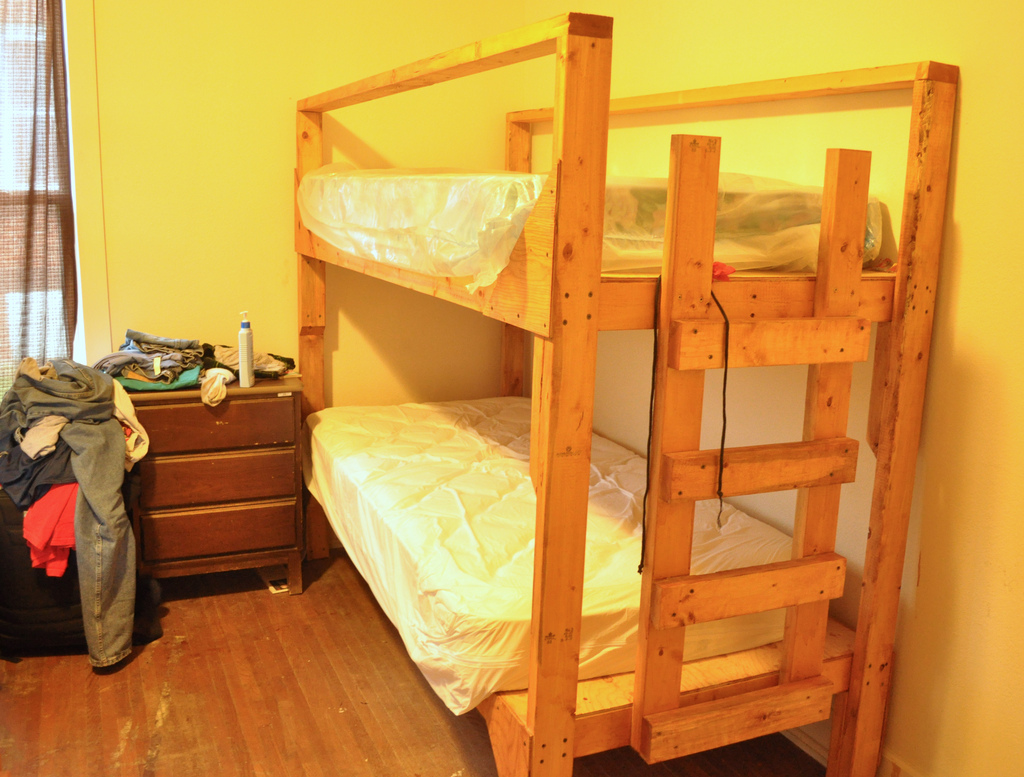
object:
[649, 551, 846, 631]
slat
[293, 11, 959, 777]
bed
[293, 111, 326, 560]
slat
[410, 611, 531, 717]
mattress protector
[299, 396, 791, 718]
mattress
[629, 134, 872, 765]
ladder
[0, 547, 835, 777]
floor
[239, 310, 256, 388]
bottle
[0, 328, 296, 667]
clothing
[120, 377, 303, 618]
dresser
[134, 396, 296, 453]
drawer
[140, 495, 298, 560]
drawer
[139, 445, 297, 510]
drawer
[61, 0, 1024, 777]
wall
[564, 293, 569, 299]
screw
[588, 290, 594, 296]
screw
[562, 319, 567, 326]
screw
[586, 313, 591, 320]
screw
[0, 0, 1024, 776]
building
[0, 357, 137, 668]
pants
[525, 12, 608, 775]
leg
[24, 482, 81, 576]
shirt